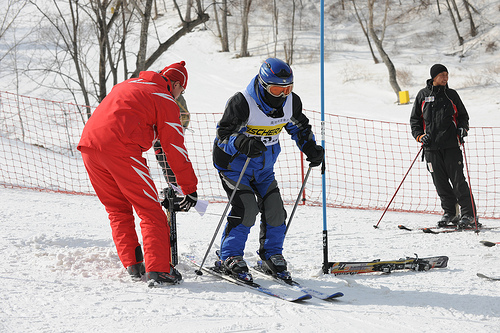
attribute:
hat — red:
[161, 64, 188, 83]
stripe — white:
[165, 68, 184, 80]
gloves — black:
[227, 129, 342, 177]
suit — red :
[104, 72, 159, 257]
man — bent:
[407, 70, 479, 227]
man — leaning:
[74, 62, 194, 283]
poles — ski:
[187, 118, 324, 280]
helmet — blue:
[244, 63, 313, 93]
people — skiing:
[49, 21, 499, 328]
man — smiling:
[405, 56, 492, 229]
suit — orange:
[73, 69, 200, 275]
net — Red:
[1, 89, 497, 221]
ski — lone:
[320, 255, 450, 275]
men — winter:
[78, 60, 495, 293]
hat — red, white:
[161, 63, 186, 86]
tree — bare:
[31, 0, 208, 122]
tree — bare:
[208, 0, 233, 52]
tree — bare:
[233, 0, 251, 56]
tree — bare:
[364, 0, 409, 102]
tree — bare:
[281, 1, 296, 66]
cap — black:
[433, 60, 450, 72]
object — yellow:
[397, 87, 411, 103]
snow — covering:
[1, 0, 499, 331]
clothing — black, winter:
[408, 78, 477, 226]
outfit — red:
[75, 70, 199, 268]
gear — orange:
[72, 61, 199, 290]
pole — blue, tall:
[320, 31, 333, 274]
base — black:
[312, 227, 337, 285]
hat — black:
[423, 58, 445, 83]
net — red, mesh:
[326, 116, 406, 219]